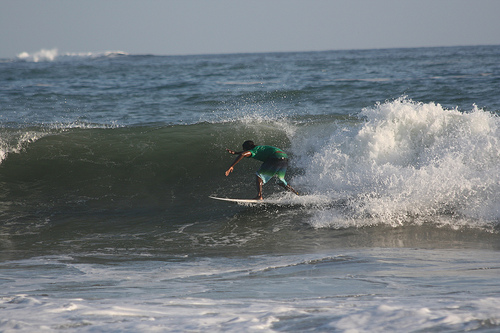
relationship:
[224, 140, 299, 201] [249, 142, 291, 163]
boy in green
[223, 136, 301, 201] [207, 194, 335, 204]
surfer on surfboard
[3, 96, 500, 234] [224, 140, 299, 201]
wave behind boy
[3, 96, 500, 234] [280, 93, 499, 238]
wave has foam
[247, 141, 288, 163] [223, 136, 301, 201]
shirt on surfer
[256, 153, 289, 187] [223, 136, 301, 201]
shorts on surfer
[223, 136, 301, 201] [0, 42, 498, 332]
surfer in ocean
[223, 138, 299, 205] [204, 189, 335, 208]
boy on surfboard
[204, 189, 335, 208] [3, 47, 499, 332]
surfboard in water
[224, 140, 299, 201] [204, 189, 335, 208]
boy on surfboard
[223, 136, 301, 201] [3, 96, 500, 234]
surfer ready to catch wave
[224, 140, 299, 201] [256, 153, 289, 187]
boy i shorts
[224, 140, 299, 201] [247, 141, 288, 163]
boy in shirt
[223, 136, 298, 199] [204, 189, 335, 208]
surfboarder standing on surfboard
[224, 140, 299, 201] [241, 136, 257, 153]
boy has head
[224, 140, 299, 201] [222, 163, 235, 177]
boy has hand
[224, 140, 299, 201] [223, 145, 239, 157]
boy has hand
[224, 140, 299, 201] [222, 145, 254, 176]
boy has arm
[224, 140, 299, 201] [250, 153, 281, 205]
boy has leg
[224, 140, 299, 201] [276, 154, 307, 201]
boy has leg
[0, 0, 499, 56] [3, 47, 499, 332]
sky over water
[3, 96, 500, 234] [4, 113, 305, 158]
wave has crest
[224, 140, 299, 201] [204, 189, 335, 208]
boy riding a surfboard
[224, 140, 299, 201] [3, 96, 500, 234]
boy riding wave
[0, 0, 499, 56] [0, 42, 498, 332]
sky above ocean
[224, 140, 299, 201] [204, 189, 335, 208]
boy riding surfboard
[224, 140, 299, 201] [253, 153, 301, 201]
boy has legs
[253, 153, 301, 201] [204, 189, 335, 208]
legs on surfboard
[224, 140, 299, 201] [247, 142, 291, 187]
boy wearing wetsuit